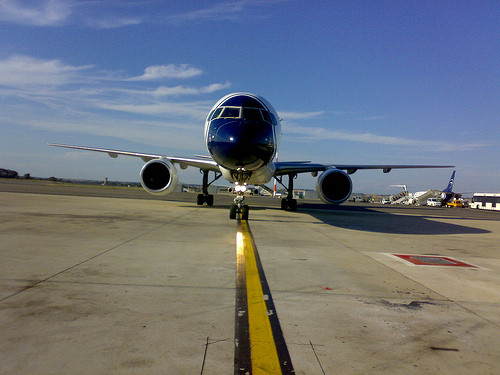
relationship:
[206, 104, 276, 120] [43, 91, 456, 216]
windows on plane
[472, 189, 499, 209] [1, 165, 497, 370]
white bus on runway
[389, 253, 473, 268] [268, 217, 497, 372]
square on ground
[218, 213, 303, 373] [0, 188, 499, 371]
lines in road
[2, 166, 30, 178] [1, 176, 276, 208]
trees on road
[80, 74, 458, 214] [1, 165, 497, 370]
airplane on runway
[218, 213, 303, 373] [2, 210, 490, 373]
lines on runway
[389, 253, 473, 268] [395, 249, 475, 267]
square on ground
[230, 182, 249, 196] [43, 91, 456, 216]
headlights on plane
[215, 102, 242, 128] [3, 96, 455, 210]
windshield on airplane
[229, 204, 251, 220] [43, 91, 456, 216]
landing gear on plane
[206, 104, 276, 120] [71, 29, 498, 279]
windows on plane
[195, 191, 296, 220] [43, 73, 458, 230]
wheels on plane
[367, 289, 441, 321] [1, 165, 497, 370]
marks on runway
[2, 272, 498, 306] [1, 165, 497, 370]
line on runway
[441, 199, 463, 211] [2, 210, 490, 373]
truck on runway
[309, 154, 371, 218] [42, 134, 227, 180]
engine under wing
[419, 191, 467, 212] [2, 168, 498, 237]
vehicles on tarmac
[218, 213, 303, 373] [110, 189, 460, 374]
lines on runway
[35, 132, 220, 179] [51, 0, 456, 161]
wing of airplane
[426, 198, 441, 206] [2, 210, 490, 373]
white van on runway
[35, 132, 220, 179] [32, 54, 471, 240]
wing on plane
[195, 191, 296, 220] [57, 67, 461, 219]
wheels on plane